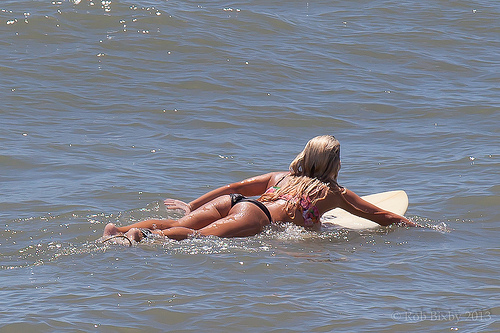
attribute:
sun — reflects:
[61, 0, 151, 32]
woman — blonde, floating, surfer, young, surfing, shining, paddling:
[99, 132, 426, 240]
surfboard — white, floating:
[320, 189, 410, 233]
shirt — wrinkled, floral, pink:
[260, 177, 322, 229]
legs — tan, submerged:
[102, 192, 270, 241]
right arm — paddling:
[335, 185, 423, 229]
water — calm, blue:
[1, 0, 499, 332]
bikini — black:
[226, 172, 322, 228]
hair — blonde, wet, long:
[256, 131, 347, 221]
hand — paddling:
[413, 223, 445, 239]